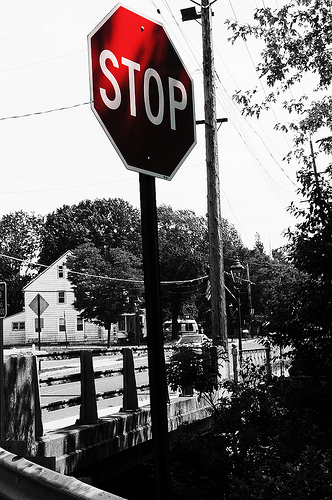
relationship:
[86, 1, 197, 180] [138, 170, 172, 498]
stop sign on pole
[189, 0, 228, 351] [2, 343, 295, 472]
telephone pole on side of bridge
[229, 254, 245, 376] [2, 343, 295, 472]
street light on bridge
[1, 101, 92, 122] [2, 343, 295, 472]
wire above bridge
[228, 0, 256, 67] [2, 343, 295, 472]
wire above bridge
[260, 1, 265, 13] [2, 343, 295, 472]
wire above bridge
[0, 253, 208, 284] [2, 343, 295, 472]
wire above bridge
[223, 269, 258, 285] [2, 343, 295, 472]
wire above bridge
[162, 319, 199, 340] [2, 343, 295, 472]
van parked in bridge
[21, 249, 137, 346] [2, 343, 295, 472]
house on bridge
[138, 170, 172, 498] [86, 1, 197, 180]
pole for stop sign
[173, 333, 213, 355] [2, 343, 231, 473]
car driving toward bridge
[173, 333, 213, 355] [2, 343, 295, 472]
car travelling on bridge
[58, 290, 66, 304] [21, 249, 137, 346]
window to house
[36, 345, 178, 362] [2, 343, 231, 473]
railing of bridge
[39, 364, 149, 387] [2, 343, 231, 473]
railing of bridge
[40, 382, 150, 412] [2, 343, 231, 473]
railing of bridge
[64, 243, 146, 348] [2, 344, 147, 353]
tree in yard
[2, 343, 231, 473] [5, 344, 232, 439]
bridge has fence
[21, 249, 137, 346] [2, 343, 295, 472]
house by bridge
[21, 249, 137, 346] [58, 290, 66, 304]
house has window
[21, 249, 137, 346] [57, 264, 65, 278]
house has window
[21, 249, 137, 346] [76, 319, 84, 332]
house has window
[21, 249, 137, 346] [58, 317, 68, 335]
house has window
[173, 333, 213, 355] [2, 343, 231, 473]
car on top of bridge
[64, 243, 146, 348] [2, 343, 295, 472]
tree growing near bridge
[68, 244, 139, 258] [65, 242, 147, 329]
edge of tree top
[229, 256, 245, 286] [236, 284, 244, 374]
lantern on top of post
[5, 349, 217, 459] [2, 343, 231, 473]
shadow on bridge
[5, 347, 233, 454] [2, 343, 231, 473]
light on bridge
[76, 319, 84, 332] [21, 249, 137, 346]
window in house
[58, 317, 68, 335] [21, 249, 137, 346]
window on house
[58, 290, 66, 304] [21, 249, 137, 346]
window on house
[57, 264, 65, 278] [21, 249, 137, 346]
window on house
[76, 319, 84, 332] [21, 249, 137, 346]
window on house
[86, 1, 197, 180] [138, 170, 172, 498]
stop sign mounted on pole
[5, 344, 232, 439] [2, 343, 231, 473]
fence on bridge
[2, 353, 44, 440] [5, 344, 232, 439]
column support for fence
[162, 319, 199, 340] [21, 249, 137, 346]
van parked at house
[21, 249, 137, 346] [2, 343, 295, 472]
house across bridge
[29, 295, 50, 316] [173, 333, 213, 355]
back facing car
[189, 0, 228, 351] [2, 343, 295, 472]
telephone pole on bridge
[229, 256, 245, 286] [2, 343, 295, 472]
lantern along bridge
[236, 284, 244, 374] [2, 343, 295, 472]
post along bridge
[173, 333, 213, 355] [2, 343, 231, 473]
car driving along bridge